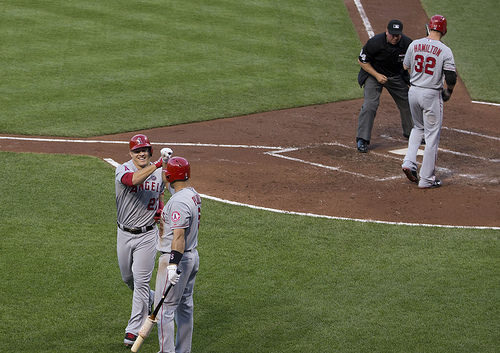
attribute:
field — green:
[4, 3, 495, 349]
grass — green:
[227, 228, 423, 328]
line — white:
[205, 140, 296, 154]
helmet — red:
[163, 154, 189, 181]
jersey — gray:
[157, 185, 200, 251]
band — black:
[169, 249, 181, 262]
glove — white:
[167, 264, 180, 283]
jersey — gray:
[115, 159, 166, 229]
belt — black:
[111, 220, 158, 233]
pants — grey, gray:
[157, 249, 200, 351]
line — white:
[293, 201, 418, 228]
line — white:
[186, 128, 287, 153]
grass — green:
[37, 23, 255, 99]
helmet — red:
[426, 10, 449, 35]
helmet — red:
[130, 133, 153, 153]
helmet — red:
[126, 129, 153, 152]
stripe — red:
[157, 300, 165, 349]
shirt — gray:
[399, 33, 460, 93]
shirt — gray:
[157, 182, 202, 256]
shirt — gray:
[113, 161, 165, 223]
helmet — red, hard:
[126, 130, 150, 157]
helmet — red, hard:
[162, 153, 194, 180]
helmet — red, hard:
[426, 9, 452, 33]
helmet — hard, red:
[123, 126, 153, 153]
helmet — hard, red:
[160, 153, 191, 180]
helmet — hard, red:
[425, 13, 447, 33]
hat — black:
[383, 17, 406, 43]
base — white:
[387, 146, 425, 157]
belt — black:
[116, 217, 161, 235]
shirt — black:
[361, 33, 409, 78]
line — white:
[196, 189, 498, 229]